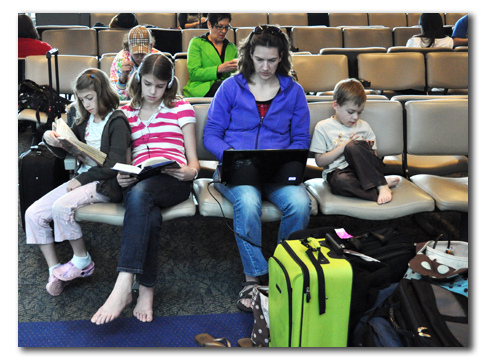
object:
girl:
[23, 68, 133, 299]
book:
[51, 117, 108, 169]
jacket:
[202, 71, 312, 163]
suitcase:
[266, 232, 354, 348]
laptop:
[220, 148, 310, 187]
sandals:
[51, 260, 97, 282]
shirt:
[119, 99, 197, 168]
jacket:
[41, 108, 132, 203]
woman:
[109, 23, 165, 101]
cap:
[125, 23, 156, 56]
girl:
[89, 51, 203, 327]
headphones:
[134, 50, 175, 89]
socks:
[70, 250, 92, 269]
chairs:
[403, 98, 469, 213]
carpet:
[17, 215, 288, 350]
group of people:
[23, 22, 398, 328]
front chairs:
[192, 103, 319, 223]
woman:
[197, 19, 317, 312]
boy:
[308, 75, 402, 205]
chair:
[305, 100, 439, 223]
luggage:
[245, 226, 475, 348]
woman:
[180, 12, 242, 98]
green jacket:
[182, 33, 240, 97]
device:
[354, 140, 374, 147]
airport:
[17, 14, 471, 349]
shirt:
[308, 115, 378, 184]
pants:
[326, 139, 390, 202]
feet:
[132, 283, 154, 323]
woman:
[17, 13, 54, 59]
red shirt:
[16, 36, 51, 58]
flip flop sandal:
[191, 331, 233, 349]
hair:
[235, 22, 294, 85]